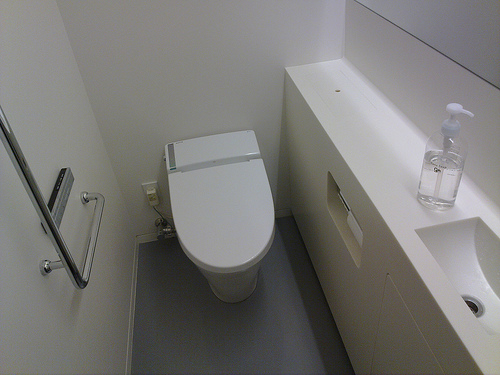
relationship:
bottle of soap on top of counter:
[415, 96, 471, 210] [282, 60, 496, 374]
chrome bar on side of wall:
[1, 109, 101, 287] [0, 1, 133, 374]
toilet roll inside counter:
[343, 209, 367, 247] [282, 60, 496, 374]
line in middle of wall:
[354, 1, 498, 99] [345, 4, 497, 198]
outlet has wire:
[142, 179, 162, 203] [152, 203, 178, 235]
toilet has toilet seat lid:
[166, 128, 275, 302] [169, 166, 274, 269]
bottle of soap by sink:
[415, 96, 471, 210] [414, 216, 500, 353]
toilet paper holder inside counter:
[329, 183, 366, 246] [282, 60, 496, 374]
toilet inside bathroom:
[166, 128, 275, 302] [2, 3, 495, 374]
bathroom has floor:
[2, 3, 495, 374] [125, 209, 352, 374]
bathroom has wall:
[2, 3, 495, 374] [0, 1, 133, 374]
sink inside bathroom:
[414, 216, 500, 353] [2, 3, 495, 374]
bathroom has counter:
[2, 3, 495, 374] [282, 60, 496, 374]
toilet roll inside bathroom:
[343, 209, 367, 247] [2, 3, 495, 374]